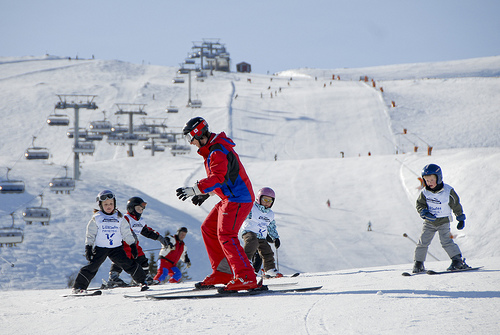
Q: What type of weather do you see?
A: It is cloudless.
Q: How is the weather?
A: It is cloudless.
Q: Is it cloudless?
A: Yes, it is cloudless.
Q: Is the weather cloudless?
A: Yes, it is cloudless.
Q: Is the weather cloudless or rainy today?
A: It is cloudless.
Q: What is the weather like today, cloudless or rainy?
A: It is cloudless.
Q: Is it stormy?
A: No, it is cloudless.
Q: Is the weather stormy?
A: No, it is cloudless.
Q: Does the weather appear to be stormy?
A: No, it is cloudless.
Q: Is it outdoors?
A: Yes, it is outdoors.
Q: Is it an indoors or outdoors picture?
A: It is outdoors.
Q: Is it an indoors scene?
A: No, it is outdoors.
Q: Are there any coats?
A: Yes, there is a coat.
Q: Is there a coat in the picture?
A: Yes, there is a coat.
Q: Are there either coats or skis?
A: Yes, there is a coat.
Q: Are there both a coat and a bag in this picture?
A: No, there is a coat but no bags.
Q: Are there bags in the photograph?
A: No, there are no bags.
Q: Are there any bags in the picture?
A: No, there are no bags.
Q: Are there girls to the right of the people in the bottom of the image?
A: Yes, there is a girl to the right of the people.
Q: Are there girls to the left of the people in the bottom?
A: No, the girl is to the right of the people.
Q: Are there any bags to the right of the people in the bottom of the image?
A: No, there is a girl to the right of the people.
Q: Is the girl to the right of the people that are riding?
A: Yes, the girl is to the right of the people.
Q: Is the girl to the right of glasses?
A: No, the girl is to the right of the people.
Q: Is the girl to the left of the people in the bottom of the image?
A: No, the girl is to the right of the people.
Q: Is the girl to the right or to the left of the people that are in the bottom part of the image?
A: The girl is to the right of the people.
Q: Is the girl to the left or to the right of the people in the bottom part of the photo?
A: The girl is to the right of the people.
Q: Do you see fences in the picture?
A: No, there are no fences.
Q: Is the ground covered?
A: Yes, the ground is covered.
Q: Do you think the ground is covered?
A: Yes, the ground is covered.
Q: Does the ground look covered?
A: Yes, the ground is covered.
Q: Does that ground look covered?
A: Yes, the ground is covered.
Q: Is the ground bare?
A: No, the ground is covered.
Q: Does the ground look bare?
A: No, the ground is covered.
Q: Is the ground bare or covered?
A: The ground is covered.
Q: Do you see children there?
A: Yes, there is a child.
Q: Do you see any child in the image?
A: Yes, there is a child.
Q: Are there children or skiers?
A: Yes, there is a child.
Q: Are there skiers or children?
A: Yes, there is a child.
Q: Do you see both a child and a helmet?
A: Yes, there are both a child and a helmet.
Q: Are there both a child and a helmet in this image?
A: Yes, there are both a child and a helmet.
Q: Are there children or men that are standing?
A: Yes, the child is standing.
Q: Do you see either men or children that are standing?
A: Yes, the child is standing.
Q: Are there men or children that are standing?
A: Yes, the child is standing.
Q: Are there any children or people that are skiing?
A: Yes, the child is skiing.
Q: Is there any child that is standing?
A: Yes, there is a child that is standing.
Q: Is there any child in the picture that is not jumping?
A: Yes, there is a child that is standing.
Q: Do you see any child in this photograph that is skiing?
A: Yes, there is a child that is skiing.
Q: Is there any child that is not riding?
A: Yes, there is a child that is skiing.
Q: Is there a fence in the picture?
A: No, there are no fences.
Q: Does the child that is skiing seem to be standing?
A: Yes, the kid is standing.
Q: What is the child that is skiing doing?
A: The child is standing.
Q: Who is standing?
A: The kid is standing.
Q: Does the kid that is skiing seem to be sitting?
A: No, the kid is standing.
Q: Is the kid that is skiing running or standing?
A: The child is standing.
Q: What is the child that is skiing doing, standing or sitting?
A: The child is standing.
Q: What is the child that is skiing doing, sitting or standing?
A: The child is standing.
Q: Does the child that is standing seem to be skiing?
A: Yes, the child is skiing.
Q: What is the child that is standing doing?
A: The kid is skiing.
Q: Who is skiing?
A: The kid is skiing.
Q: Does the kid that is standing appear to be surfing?
A: No, the kid is skiing.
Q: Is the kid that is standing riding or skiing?
A: The kid is skiing.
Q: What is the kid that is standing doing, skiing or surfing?
A: The child is skiing.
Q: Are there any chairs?
A: Yes, there is a chair.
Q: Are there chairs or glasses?
A: Yes, there is a chair.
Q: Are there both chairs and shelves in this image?
A: No, there is a chair but no shelves.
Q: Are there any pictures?
A: No, there are no pictures.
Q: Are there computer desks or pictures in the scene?
A: No, there are no pictures or computer desks.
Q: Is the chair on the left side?
A: Yes, the chair is on the left of the image.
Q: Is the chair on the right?
A: No, the chair is on the left of the image.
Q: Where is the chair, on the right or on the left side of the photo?
A: The chair is on the left of the image.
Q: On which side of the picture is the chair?
A: The chair is on the left of the image.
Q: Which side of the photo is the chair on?
A: The chair is on the left of the image.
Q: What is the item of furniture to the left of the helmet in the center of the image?
A: The piece of furniture is a chair.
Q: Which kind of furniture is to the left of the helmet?
A: The piece of furniture is a chair.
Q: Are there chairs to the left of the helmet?
A: Yes, there is a chair to the left of the helmet.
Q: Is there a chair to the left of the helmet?
A: Yes, there is a chair to the left of the helmet.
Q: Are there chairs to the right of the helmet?
A: No, the chair is to the left of the helmet.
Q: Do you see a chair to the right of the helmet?
A: No, the chair is to the left of the helmet.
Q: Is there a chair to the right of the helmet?
A: No, the chair is to the left of the helmet.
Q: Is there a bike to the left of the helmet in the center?
A: No, there is a chair to the left of the helmet.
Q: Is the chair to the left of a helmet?
A: Yes, the chair is to the left of a helmet.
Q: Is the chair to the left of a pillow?
A: No, the chair is to the left of a helmet.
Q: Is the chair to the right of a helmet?
A: No, the chair is to the left of a helmet.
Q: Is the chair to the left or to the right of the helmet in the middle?
A: The chair is to the left of the helmet.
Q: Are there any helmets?
A: Yes, there is a helmet.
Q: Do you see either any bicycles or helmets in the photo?
A: Yes, there is a helmet.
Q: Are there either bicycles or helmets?
A: Yes, there is a helmet.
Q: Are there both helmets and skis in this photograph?
A: Yes, there are both a helmet and skis.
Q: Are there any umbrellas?
A: No, there are no umbrellas.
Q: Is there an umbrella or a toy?
A: No, there are no umbrellas or toys.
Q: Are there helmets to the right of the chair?
A: Yes, there is a helmet to the right of the chair.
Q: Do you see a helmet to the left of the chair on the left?
A: No, the helmet is to the right of the chair.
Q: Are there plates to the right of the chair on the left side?
A: No, there is a helmet to the right of the chair.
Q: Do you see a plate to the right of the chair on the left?
A: No, there is a helmet to the right of the chair.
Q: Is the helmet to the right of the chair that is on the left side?
A: Yes, the helmet is to the right of the chair.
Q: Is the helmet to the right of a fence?
A: No, the helmet is to the right of the chair.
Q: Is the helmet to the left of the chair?
A: No, the helmet is to the right of the chair.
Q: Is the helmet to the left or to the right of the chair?
A: The helmet is to the right of the chair.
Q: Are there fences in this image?
A: No, there are no fences.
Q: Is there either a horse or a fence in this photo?
A: No, there are no fences or horses.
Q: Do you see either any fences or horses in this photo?
A: No, there are no fences or horses.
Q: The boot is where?
A: The boot is in the snow.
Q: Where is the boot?
A: The boot is in the snow.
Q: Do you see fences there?
A: No, there are no fences.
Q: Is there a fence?
A: No, there are no fences.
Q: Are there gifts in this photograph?
A: No, there are no gifts.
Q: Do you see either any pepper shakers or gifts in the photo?
A: No, there are no gifts or pepper shakers.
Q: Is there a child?
A: Yes, there is a child.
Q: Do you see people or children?
A: Yes, there is a child.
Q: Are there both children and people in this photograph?
A: Yes, there are both a child and people.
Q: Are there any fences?
A: No, there are no fences.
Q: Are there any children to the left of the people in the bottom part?
A: Yes, there is a child to the left of the people.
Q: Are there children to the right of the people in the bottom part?
A: No, the child is to the left of the people.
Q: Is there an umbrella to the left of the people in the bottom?
A: No, there is a child to the left of the people.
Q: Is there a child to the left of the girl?
A: Yes, there is a child to the left of the girl.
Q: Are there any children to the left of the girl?
A: Yes, there is a child to the left of the girl.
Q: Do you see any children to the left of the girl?
A: Yes, there is a child to the left of the girl.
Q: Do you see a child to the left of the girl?
A: Yes, there is a child to the left of the girl.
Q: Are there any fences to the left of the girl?
A: No, there is a child to the left of the girl.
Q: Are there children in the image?
A: Yes, there are children.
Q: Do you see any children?
A: Yes, there are children.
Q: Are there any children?
A: Yes, there are children.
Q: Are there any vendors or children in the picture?
A: Yes, there are children.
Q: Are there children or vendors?
A: Yes, there are children.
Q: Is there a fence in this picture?
A: No, there are no fences.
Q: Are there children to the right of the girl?
A: No, the children are to the left of the girl.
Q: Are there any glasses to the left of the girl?
A: No, there are children to the left of the girl.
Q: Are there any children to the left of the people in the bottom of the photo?
A: Yes, there are children to the left of the people.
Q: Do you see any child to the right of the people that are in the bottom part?
A: No, the children are to the left of the people.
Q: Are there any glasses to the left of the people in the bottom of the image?
A: No, there are children to the left of the people.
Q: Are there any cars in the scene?
A: No, there are no cars.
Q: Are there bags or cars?
A: No, there are no cars or bags.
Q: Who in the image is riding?
A: The people are riding.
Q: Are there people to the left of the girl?
A: Yes, there are people to the left of the girl.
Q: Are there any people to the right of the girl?
A: No, the people are to the left of the girl.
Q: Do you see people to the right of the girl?
A: No, the people are to the left of the girl.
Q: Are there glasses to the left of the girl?
A: No, there are people to the left of the girl.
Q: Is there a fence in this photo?
A: No, there are no fences.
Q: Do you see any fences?
A: No, there are no fences.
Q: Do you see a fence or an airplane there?
A: No, there are no fences or airplanes.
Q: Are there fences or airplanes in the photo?
A: No, there are no fences or airplanes.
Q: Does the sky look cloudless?
A: Yes, the sky is cloudless.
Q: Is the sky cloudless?
A: Yes, the sky is cloudless.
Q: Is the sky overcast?
A: No, the sky is cloudless.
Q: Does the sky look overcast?
A: No, the sky is cloudless.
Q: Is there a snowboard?
A: No, there are no snowboards.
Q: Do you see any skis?
A: Yes, there are skis.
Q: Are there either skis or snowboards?
A: Yes, there are skis.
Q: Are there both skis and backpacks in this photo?
A: No, there are skis but no backpacks.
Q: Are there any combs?
A: No, there are no combs.